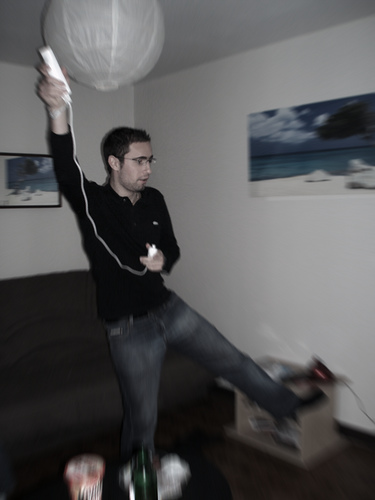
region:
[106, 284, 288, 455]
man wearing blue jeans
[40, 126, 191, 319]
man wearing long sleeved black shirt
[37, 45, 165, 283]
man holding white wii control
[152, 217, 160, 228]
izod emblem on man's shirt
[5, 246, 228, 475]
brown couch in background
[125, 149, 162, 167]
glasses on man's face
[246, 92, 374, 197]
the painting is hanging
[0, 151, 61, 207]
the picture is hanging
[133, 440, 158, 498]
the green glass bottle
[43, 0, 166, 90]
the white paper lantern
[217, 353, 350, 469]
the short light colored stand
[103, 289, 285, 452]
the dark blue jeans with faded areas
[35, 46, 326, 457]
the man holding wii controllers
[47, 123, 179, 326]
the long sleeved black shirt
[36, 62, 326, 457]
the man wearing a pair of glasses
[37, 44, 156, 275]
the white whii controllers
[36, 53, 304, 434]
man in black shirt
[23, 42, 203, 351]
man holding white wii remote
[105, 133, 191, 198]
man in glasses playing wii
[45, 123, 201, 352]
man wearing black shirt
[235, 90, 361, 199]
beach painting on wall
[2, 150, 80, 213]
framed picture on wall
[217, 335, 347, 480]
tan shelf by man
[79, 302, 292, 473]
jeans worn by man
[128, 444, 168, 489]
green bottle in front of man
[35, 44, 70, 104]
White Wii controller in man's hand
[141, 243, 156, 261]
White end of Wii controller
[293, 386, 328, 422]
Blurred foot on man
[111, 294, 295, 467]
Black jeans on man's legs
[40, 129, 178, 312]
Black shirt on a man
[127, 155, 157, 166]
Glasses on a man's face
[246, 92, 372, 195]
Picture hanging on a wall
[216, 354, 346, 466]
Small tan shelf on floor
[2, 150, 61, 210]
Framed picture on a wall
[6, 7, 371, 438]
room with white walls and white ceiling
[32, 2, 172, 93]
round and white paper lantern hanging from ceiling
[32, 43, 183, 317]
man holding remote controls for electronic game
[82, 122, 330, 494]
man standing on one leg with other stretched to side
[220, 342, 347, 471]
small tan table holding items behind foot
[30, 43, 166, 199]
one arm lifted over head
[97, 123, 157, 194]
man with dark hair and unshaven face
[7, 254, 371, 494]
dark sofa and flooring in room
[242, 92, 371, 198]
picture of sky, ocean and beach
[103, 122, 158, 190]
eyeglasses on head and eyes looking ahead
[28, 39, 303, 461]
A man playing a video game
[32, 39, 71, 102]
A white game controller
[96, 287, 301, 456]
A pair of dark jeans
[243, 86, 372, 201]
Painting on the wall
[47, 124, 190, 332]
A guy wearing a black shirt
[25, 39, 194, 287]
a guy holding a Wii controller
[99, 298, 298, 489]
the mans legs below torso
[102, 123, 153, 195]
the mans head above shoulders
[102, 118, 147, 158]
the hair on the mans head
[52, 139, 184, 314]
the mans shirt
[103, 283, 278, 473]
the mans pants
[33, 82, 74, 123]
the mans hand at end of arm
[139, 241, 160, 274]
part of the wii controller in his hand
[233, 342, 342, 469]
table that is on floor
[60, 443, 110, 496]
cup of something near right leg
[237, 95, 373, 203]
picture on wall